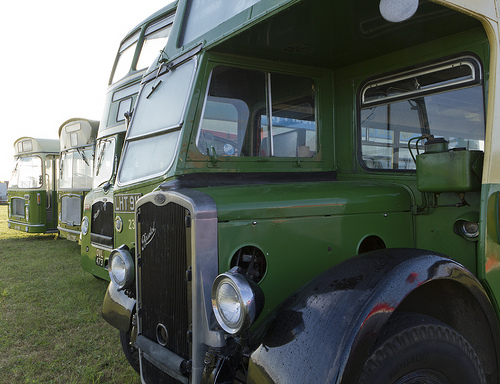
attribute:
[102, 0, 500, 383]
bus — green, two level, here, big, parked, second tiered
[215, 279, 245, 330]
light — mounted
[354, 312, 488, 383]
tire — rubber, big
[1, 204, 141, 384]
grass — green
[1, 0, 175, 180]
sky — grey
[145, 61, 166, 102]
wiper — small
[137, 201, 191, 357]
grill — black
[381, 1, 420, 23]
mirror — hanging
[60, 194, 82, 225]
grill — chrome